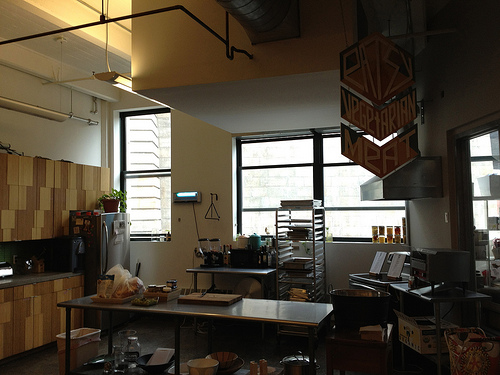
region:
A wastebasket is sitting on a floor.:
[52, 324, 104, 374]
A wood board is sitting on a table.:
[173, 286, 243, 313]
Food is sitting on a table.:
[87, 262, 172, 314]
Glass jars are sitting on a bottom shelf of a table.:
[97, 332, 145, 374]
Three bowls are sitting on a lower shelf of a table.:
[135, 344, 243, 374]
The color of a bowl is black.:
[134, 346, 176, 374]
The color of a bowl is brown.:
[200, 348, 245, 374]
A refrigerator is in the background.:
[65, 204, 133, 340]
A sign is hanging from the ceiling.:
[336, 29, 423, 181]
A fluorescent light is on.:
[85, 66, 176, 114]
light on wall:
[169, 185, 206, 209]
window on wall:
[110, 110, 176, 247]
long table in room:
[47, 268, 347, 373]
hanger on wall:
[199, 191, 228, 227]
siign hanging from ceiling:
[318, 0, 453, 193]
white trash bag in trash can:
[44, 318, 113, 362]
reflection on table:
[237, 295, 299, 324]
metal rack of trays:
[262, 187, 338, 350]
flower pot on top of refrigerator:
[93, 182, 131, 213]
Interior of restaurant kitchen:
[29, 0, 446, 372]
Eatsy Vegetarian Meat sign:
[328, 28, 424, 180]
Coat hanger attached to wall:
[201, 182, 223, 224]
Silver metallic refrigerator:
[69, 213, 134, 272]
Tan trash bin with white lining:
[53, 328, 103, 366]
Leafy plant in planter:
[98, 189, 125, 212]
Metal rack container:
[271, 197, 328, 301]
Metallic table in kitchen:
[58, 264, 337, 374]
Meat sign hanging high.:
[336, 24, 421, 175]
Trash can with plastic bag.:
[57, 322, 103, 365]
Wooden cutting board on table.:
[174, 288, 240, 308]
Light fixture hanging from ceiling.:
[93, 70, 142, 93]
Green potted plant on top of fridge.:
[96, 189, 128, 216]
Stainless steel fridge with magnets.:
[69, 211, 136, 265]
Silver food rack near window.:
[274, 200, 324, 300]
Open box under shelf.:
[396, 311, 436, 351]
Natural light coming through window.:
[239, 139, 313, 194]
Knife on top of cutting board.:
[196, 283, 212, 298]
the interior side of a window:
[118, 109, 171, 245]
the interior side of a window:
[236, 140, 316, 235]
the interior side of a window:
[323, 136, 402, 243]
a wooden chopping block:
[181, 290, 240, 307]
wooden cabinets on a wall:
[0, 156, 109, 240]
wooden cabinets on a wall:
[4, 273, 81, 362]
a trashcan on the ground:
[58, 327, 100, 372]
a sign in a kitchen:
[336, 34, 422, 181]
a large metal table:
[61, 291, 332, 373]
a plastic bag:
[101, 260, 145, 298]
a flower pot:
[88, 185, 134, 220]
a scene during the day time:
[8, 24, 477, 374]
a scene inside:
[9, 23, 494, 371]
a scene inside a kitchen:
[16, 28, 495, 368]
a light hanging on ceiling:
[76, 37, 164, 131]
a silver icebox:
[61, 200, 139, 343]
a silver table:
[50, 268, 347, 372]